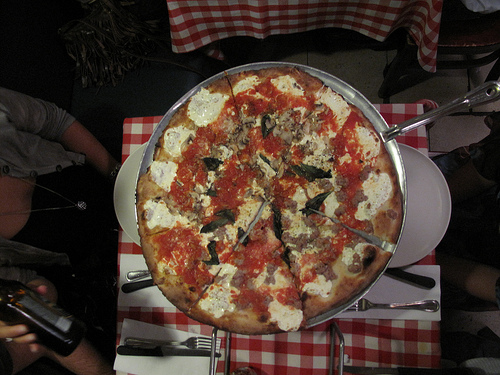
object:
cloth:
[113, 104, 445, 375]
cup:
[135, 59, 405, 336]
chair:
[113, 102, 441, 375]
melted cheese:
[162, 86, 231, 158]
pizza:
[133, 66, 404, 336]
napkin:
[334, 264, 442, 322]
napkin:
[111, 317, 221, 375]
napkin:
[117, 252, 174, 308]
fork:
[347, 297, 440, 312]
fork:
[116, 336, 222, 359]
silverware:
[379, 80, 499, 145]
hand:
[0, 279, 63, 354]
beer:
[0, 277, 87, 359]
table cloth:
[111, 104, 442, 375]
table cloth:
[165, 0, 442, 73]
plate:
[388, 142, 452, 270]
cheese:
[291, 187, 308, 204]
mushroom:
[200, 210, 236, 233]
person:
[0, 85, 117, 374]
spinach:
[289, 161, 334, 218]